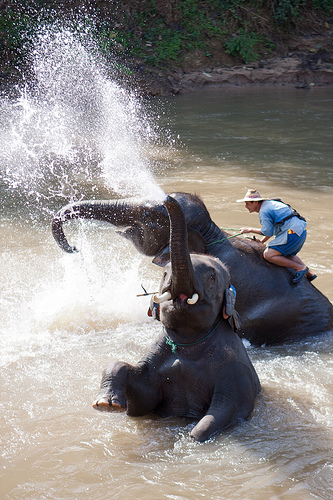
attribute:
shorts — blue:
[268, 224, 332, 265]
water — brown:
[15, 255, 322, 487]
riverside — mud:
[11, 56, 331, 93]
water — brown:
[0, 146, 332, 498]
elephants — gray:
[50, 181, 330, 442]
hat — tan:
[237, 188, 270, 202]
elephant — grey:
[24, 181, 331, 359]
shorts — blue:
[268, 228, 307, 258]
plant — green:
[128, 11, 249, 52]